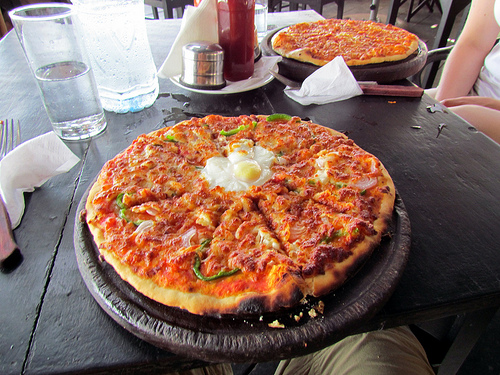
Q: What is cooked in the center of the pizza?
A: Egg.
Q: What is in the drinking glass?
A: Water.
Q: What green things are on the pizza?
A: Bell pepper slices.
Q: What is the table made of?
A: Wood.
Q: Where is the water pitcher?
A: Beside the water glass.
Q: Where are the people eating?
A: At a restaurant.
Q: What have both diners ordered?
A: Pizza.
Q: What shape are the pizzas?
A: Circles.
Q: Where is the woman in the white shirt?
A: Seated on the right.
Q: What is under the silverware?
A: Napkins.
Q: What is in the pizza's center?
A: Egg.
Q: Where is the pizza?
A: Wood platter.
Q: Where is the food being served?
A: Patio.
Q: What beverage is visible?
A: Water.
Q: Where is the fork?
A: In a napkin.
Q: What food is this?
A: Pizza.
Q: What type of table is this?
A: Wood picnic table.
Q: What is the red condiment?
A: Ketchup.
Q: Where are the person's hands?
A: Lap.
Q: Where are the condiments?
A: White plate.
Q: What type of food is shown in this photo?
A: Deep dish pizza.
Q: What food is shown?
A: Pizza.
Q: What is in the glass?
A: Water.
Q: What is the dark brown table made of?
A: Wood.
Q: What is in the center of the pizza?
A: Egg.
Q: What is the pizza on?
A: Brown platter.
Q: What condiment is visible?
A: Catsup.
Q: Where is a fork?
A: Napkin next to pizza.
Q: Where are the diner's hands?
A: Lap.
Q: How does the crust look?
A: Burnt.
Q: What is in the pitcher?
A: Water.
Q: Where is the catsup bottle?
A: Small dish on table.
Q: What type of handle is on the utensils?
A: Wood.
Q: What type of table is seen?
A: Brown wood.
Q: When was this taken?
A: Daytime.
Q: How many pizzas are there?
A: 2.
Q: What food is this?
A: Pizza.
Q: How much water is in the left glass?
A: Half.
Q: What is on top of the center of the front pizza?
A: An egg.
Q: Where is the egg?
A: In the center of the pizza.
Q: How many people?
A: 2.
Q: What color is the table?
A: Brown.